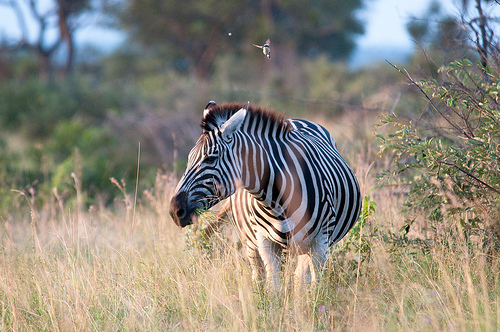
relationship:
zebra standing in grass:
[167, 100, 362, 318] [0, 176, 499, 332]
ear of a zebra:
[201, 100, 216, 125] [167, 100, 362, 318]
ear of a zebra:
[221, 100, 250, 133] [167, 100, 362, 318]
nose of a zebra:
[168, 195, 187, 221] [93, 59, 429, 304]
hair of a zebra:
[199, 101, 293, 131] [167, 100, 362, 318]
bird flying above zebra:
[252, 38, 271, 60] [148, 99, 378, 302]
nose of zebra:
[162, 172, 216, 241] [130, 77, 432, 313]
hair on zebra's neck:
[226, 104, 280, 134] [234, 127, 282, 199]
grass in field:
[38, 223, 158, 290] [43, 219, 490, 299]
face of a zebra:
[164, 123, 237, 232] [167, 100, 362, 318]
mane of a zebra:
[198, 100, 292, 130] [167, 100, 362, 318]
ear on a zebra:
[223, 102, 245, 142] [167, 92, 356, 264]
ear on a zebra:
[204, 100, 215, 118] [167, 92, 356, 264]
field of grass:
[1, 131, 496, 329] [4, 110, 496, 325]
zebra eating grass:
[167, 100, 362, 318] [33, 216, 158, 330]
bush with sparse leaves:
[363, 53, 499, 260] [389, 120, 469, 190]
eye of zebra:
[200, 155, 217, 163] [167, 100, 362, 318]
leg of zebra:
[258, 232, 286, 322] [167, 100, 362, 318]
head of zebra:
[167, 96, 249, 227] [167, 100, 362, 318]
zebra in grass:
[159, 76, 410, 261] [4, 110, 496, 325]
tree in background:
[115, 0, 365, 86] [2, 66, 499, 321]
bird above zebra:
[250, 36, 276, 60] [167, 100, 362, 318]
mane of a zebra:
[200, 100, 287, 135] [167, 61, 410, 283]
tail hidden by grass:
[187, 201, 234, 242] [0, 176, 499, 332]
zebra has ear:
[167, 100, 362, 318] [221, 100, 255, 136]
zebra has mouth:
[167, 100, 362, 318] [169, 192, 199, 231]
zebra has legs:
[167, 100, 362, 318] [238, 245, 346, 330]